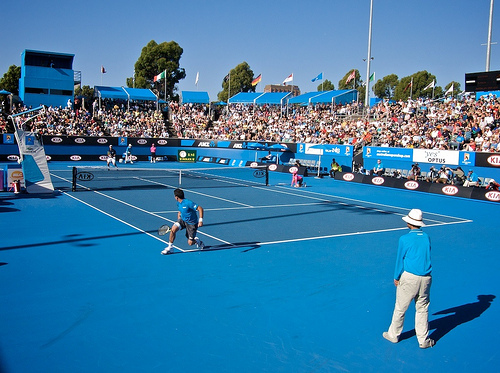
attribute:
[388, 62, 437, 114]
tree — green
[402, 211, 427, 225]
hat — white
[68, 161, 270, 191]
net — black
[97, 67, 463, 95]
flags — small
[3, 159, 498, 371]
court — blue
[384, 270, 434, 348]
pants — white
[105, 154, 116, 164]
shorts — white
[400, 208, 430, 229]
hat — white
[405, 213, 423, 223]
band — black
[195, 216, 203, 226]
armband — thick, white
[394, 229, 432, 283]
shirt — blue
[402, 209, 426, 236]
hat — white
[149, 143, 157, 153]
shirt — pink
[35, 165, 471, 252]
lines — white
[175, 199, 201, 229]
shirt — blue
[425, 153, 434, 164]
letter — black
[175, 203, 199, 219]
shirt — blue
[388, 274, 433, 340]
pants — white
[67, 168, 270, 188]
net — white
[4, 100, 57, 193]
booth — empty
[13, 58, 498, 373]
day —  bright, sunny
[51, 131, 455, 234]
lines — white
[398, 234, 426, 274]
shirt — blue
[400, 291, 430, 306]
pants — white